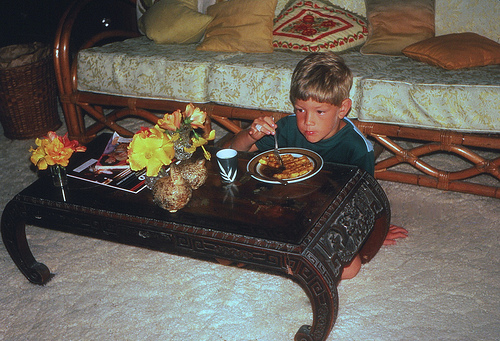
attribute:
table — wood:
[7, 134, 394, 339]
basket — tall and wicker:
[0, 36, 68, 144]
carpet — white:
[414, 217, 478, 303]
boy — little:
[221, 52, 377, 169]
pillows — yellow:
[133, 0, 495, 82]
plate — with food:
[247, 144, 324, 186]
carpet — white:
[0, 97, 499, 339]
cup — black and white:
[210, 147, 255, 191]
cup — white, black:
[216, 147, 240, 184]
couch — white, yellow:
[80, 50, 245, 104]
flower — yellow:
[177, 100, 214, 144]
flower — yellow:
[152, 109, 186, 135]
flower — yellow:
[123, 131, 182, 190]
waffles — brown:
[255, 146, 315, 191]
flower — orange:
[20, 131, 90, 176]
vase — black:
[39, 155, 75, 206]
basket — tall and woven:
[2, 50, 63, 139]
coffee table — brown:
[104, 196, 326, 268]